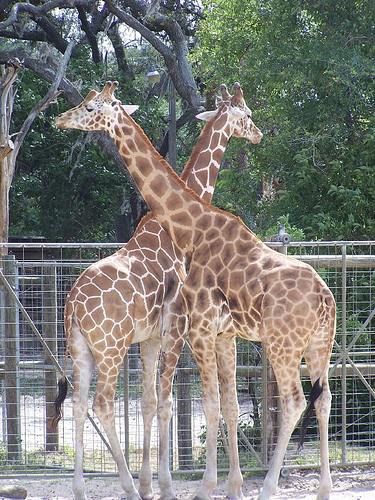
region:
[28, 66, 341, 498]
two giraffes in a pen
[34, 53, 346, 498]
two giraffes are brown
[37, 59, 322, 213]
two heads facing in different directions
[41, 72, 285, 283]
necks of giraffes forming an X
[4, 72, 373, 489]
giraffes are enclosed in a pen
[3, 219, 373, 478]
fence behind two giraffes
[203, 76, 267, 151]
horns on head of giraffe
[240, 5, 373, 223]
a tree behind a pen of giraffes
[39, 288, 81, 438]
tail of giraffe has black turf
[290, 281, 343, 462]
tail of giraffe has a black turf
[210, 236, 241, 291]
brown spots on the giraffe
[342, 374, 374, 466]
a wire metal fence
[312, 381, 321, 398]
black hair on the tail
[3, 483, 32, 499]
a large rock on the ground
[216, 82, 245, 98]
horns on the giraffe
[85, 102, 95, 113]
eye on a head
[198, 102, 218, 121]
a large pointy ear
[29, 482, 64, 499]
dirt on the ground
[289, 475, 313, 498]
dirt near the fence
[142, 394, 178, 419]
knobbly knees on the giraffe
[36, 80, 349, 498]
two giraffes standing beside each other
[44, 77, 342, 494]
the giraffes are brown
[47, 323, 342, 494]
the giraffes have long legs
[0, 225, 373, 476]
a metal fence in front of the giraffes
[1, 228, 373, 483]
the fence is silver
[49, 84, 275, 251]
the giraffes have long necks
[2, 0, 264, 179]
tree branches in front of the giraffes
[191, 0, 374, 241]
big green trees in front of the giraffes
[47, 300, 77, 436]
the tip of the giraffe's tail is black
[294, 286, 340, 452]
the giraffe has a long tail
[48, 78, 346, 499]
Giraffes standing with necks crossed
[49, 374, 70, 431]
Dark black colored tail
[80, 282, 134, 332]
White and black patches on the skin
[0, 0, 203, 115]
Thick intertwined branches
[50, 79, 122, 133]
Head of a giraffe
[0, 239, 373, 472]
Square-wired metal fence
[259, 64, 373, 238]
Lush green leaves of a tree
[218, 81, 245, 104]
Blunt horns of a giraffe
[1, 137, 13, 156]
Stump of a dry tree branch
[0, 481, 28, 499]
Large smooth stone on the ground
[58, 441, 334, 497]
Giraffe hooves in the sand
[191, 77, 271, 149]
Giraffe's head pointed away from the camera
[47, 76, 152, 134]
Giraffe's head pointed to the left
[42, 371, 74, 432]
Black giraffe's tail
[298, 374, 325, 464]
Black giraffe's tail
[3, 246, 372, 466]
Wire and wood fence in front of the giraffes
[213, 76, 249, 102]
Small giraffe horns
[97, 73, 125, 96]
Small giraffe horns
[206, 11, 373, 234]
Tall green trees in the background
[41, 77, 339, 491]
Two tall brown and white giraffes